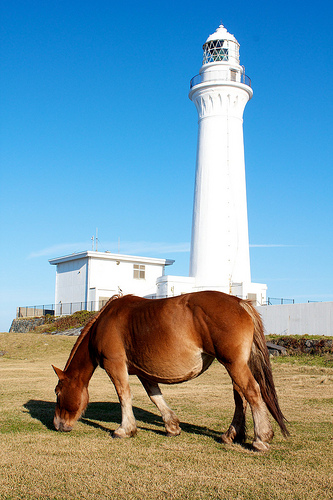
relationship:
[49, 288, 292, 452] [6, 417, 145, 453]
horse eating grass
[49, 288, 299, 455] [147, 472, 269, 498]
horse grazing grass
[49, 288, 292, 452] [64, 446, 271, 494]
horse grazing grass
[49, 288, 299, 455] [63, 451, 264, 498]
horse grazing grass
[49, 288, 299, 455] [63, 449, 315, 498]
horse grazing grass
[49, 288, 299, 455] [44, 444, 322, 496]
horse grazing grass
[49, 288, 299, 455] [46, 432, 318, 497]
horse grazing grass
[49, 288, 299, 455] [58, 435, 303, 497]
horse grazing grass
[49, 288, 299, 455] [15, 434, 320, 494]
horse grazing grass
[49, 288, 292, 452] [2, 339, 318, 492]
horse grazing grass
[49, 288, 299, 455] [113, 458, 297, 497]
horse grazing grass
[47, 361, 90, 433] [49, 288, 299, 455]
head of horse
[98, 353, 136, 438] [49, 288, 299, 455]
leg of horse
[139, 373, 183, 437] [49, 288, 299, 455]
leg of horse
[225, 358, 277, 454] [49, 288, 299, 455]
leg of horse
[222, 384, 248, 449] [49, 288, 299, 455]
leg of horse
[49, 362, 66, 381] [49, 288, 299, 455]
ear of horse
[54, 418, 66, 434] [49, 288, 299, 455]
mouth of horse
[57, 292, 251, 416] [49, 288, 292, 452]
fur of horse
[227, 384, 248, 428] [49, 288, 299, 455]
leg of horse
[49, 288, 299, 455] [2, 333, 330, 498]
horse grazing on grass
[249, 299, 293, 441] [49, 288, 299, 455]
tail of horse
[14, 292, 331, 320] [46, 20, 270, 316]
fence around buildings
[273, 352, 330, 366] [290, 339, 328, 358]
vegetation around rocks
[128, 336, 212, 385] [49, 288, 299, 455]
belly of horse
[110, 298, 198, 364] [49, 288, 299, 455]
fur on side of horse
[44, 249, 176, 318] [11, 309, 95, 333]
building on top of hill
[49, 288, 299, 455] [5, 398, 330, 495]
horse eating grass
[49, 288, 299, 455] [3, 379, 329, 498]
horse eating grass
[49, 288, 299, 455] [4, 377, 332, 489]
horse eating grass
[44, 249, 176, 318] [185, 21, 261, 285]
building next to light house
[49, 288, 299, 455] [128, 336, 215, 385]
horse has belly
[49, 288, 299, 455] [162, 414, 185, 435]
horse has hoof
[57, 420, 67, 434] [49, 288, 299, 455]
mouth of horse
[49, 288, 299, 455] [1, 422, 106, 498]
horse eating grass